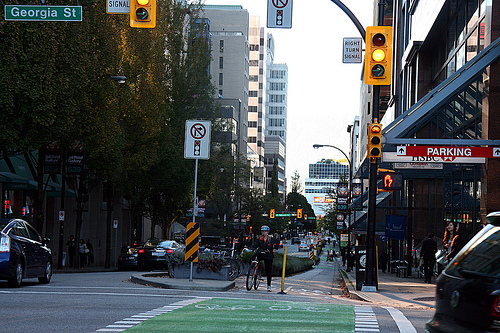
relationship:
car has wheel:
[2, 212, 28, 278] [42, 255, 54, 283]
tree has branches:
[85, 29, 182, 193] [61, 48, 102, 101]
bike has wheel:
[246, 248, 268, 293] [244, 262, 255, 291]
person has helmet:
[257, 223, 277, 286] [260, 224, 270, 232]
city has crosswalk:
[2, 3, 499, 332] [54, 272, 395, 333]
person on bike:
[257, 223, 277, 286] [246, 248, 268, 293]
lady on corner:
[436, 221, 468, 267] [367, 279, 438, 309]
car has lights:
[2, 212, 28, 278] [2, 233, 12, 256]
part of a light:
[375, 41, 396, 70] [130, 1, 159, 15]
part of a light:
[375, 41, 396, 70] [367, 45, 392, 64]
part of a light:
[375, 41, 396, 70] [369, 122, 384, 142]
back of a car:
[429, 210, 498, 330] [431, 210, 500, 333]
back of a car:
[429, 210, 498, 330] [2, 212, 28, 278]